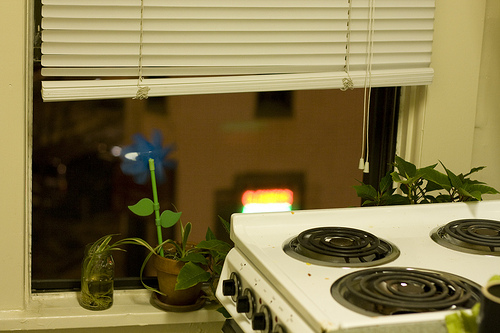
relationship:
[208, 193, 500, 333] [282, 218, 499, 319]
electric range has three burners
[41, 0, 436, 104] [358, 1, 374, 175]
mini blinds have strings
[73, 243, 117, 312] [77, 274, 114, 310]
glass filled with water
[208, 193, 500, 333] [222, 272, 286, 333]
electric range has knobs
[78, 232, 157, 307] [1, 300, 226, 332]
plant on windowsill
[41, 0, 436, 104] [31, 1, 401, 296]
mini blinds in window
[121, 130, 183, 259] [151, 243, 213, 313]
flower in pot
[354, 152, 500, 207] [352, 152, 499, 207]
plant has green leaves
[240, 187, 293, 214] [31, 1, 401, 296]
sign outside window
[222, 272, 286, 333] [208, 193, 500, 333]
knobs on electric range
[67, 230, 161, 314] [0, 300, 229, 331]
plant on window sill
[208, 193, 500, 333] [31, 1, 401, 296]
electric range beside a window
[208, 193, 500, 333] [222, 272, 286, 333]
electric range with knobs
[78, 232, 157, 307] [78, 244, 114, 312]
plant in glass